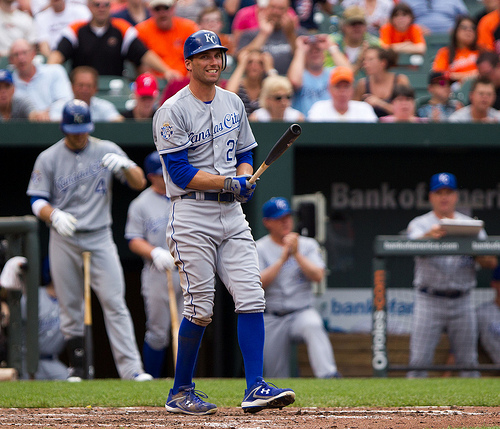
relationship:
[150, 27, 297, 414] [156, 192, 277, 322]
baseball player wearing gray pants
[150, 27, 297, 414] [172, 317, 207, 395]
baseball player wearing blue sock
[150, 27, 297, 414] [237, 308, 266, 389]
baseball player wearing blue sock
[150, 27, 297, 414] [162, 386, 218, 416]
baseball player wearing blue shoe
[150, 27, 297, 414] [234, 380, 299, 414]
baseball player wearing blue shoe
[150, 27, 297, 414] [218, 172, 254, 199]
baseball player wearing glove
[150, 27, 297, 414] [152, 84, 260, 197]
baseball player wearing jersey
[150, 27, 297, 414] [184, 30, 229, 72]
baseball player wearing baseball cap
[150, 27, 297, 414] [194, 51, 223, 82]
baseball player with man is smiling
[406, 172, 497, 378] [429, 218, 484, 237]
coach holding clipboard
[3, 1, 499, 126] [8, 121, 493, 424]
crowd watching game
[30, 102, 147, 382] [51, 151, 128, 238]
man wearing wearing white gloves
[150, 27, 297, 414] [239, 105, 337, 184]
baseball player up to bat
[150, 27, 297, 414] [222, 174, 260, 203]
baseball player wearing blue and gray gloves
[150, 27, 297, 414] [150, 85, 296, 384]
baseball player wearing blue based uniform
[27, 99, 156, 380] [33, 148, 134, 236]
man wearing wearing white gloves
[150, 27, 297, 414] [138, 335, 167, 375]
baseball player wearing wearing blue socks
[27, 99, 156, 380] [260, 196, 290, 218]
man wearing blue baseball cap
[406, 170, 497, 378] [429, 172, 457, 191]
coach wearing baseball cap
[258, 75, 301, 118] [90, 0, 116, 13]
woman wearing dark sunglasses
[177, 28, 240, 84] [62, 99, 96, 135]
player's head wearing baseball cap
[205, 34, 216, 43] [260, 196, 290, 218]
white print on blue baseball cap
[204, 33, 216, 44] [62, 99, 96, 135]
white print on baseball cap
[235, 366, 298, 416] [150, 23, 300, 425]
blue and white cleat on baseball player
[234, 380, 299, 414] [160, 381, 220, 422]
blue shoe on player's feet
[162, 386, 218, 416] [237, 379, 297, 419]
blue shoe on player's feet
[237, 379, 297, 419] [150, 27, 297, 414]
player's feet on baseball player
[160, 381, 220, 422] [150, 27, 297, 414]
player's feet on baseball player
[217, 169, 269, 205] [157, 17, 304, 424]
blue and gray gloves on player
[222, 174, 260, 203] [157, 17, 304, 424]
blue and gray gloves on player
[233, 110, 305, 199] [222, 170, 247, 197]
baseball bat in hand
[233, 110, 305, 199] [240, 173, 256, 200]
baseball bat in hand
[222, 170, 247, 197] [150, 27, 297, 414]
hand of baseball player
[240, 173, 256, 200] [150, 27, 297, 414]
hand of baseball player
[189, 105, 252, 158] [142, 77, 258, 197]
blue text of jersey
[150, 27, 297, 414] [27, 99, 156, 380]
baseball player on man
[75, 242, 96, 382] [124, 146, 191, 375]
bat on player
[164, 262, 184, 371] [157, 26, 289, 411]
bat on player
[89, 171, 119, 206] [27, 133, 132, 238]
number four on jersey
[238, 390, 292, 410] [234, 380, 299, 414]
white bottom on blue shoe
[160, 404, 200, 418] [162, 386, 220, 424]
white bottom on blue shoe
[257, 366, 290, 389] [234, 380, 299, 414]
blue shoelace on blue shoe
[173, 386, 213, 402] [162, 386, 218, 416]
blue shoelace on blue shoe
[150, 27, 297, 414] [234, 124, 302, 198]
baseball player holding baseball bat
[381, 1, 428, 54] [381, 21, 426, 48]
man wearing shirt